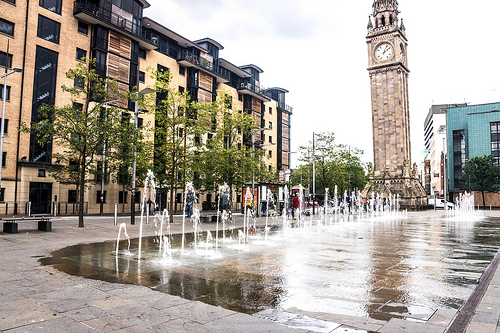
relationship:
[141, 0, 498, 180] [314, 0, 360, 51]
clouds in sky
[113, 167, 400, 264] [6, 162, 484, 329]
fountains in plaza area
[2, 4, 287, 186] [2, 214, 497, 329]
building along plaza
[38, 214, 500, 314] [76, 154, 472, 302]
water draining from fountains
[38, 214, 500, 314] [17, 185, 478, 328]
water on stones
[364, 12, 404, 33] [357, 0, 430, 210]
spires on top of clock tower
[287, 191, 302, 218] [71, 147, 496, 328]
people walking near fountains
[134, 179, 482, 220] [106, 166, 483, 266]
water spraying from fountain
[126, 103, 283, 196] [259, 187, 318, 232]
trees next to person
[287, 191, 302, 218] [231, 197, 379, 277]
people on ground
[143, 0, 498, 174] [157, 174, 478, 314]
sky above land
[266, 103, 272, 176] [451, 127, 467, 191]
windows on windows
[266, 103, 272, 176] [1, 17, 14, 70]
windows on windows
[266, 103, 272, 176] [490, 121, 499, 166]
windows on windows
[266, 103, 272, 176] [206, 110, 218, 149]
windows on windows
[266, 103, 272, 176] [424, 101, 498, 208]
windows on building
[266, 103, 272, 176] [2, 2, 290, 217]
windows on building